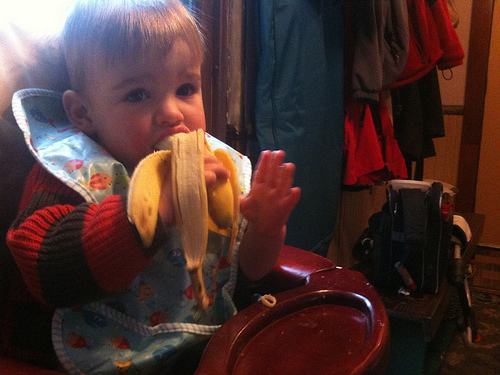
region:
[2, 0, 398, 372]
The boy is sitting in a highchair.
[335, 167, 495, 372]
The backpack is sitting on a bench.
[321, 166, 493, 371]
The bench is wood.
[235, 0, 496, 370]
Coats hanging on wall above bench.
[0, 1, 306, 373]
The boy is wearing a bib.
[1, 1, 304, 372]
The boy is eating a banana.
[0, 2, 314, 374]
The banana is partially peeled.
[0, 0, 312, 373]
The boy is wearing a sweater.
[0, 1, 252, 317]
The boy has hair.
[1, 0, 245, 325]
The boy's hair is short.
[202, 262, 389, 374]
Red tray on high chair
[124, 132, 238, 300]
Yellow banana in child's hand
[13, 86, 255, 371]
Large bib with cartoon fish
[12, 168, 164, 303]
Red and black sweater on boy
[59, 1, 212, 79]
Toddler's light brown hair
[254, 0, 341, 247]
Blue garment bag hanging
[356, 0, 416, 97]
Brown coat hanging up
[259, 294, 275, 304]
Stringy part of banana peel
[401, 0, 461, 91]
Red coat hanging up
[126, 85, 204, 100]
Little boy's brown eyes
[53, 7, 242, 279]
a young boy eating a banana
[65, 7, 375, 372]
a young boy in a high chair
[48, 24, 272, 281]
a young boy wearing a bib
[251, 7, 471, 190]
several coats hanging on the wall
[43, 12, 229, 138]
a young boy with blonde hair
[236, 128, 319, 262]
a young child's hand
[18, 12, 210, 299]
a young boy wearing a red and black sweater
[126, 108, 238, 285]
a half peeled banana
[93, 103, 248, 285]
a yellow banana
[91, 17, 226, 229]
a young boy with a banana in his mouth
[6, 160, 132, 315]
The baby has his arm bent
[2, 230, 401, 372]
The color of the high chair is burgundy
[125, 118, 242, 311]
A banana is being eaten by a child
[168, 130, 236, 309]
The peel of the banana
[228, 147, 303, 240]
The hand of the toddler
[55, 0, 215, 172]
The head of the toddler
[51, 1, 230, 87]
The child's hair is blonde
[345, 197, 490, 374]
The bench is dark brown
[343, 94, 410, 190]
The hanging garment is red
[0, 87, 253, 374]
The bib on the toddler is blue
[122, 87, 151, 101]
child's right eye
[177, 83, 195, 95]
child's left eye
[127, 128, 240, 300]
banana in a baby's mouth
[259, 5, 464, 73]
coats hanging from a coat rack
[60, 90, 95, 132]
a baby's right ear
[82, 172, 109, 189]
an orange cartoon goldfish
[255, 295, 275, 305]
part of a banana peel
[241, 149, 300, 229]
a baby's left hand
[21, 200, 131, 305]
the arm of a child's black and red sweater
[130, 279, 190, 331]
part of a child's bib featuring cartoon fish on a blue background